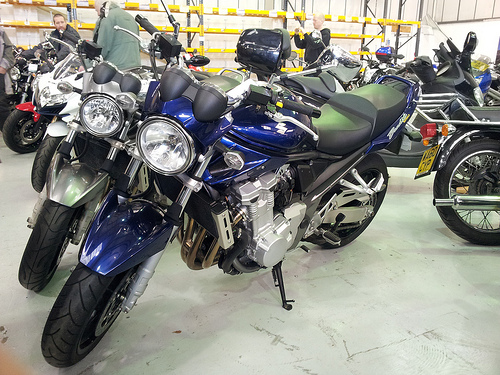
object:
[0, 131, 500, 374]
floor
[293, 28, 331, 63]
black shirt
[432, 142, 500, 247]
wheel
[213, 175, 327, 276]
engine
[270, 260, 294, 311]
kickstand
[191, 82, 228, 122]
black lights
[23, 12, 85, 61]
man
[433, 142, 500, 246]
tire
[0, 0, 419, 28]
railing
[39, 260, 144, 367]
tire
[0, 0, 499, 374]
warehouse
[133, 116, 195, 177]
unlit headlights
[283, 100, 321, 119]
handle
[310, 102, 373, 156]
seat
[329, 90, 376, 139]
divider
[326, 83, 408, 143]
seating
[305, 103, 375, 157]
seating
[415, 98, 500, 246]
mototrcycle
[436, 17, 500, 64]
doorway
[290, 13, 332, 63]
man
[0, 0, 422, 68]
wall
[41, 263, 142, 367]
wheel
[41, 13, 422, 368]
bike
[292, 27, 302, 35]
hands